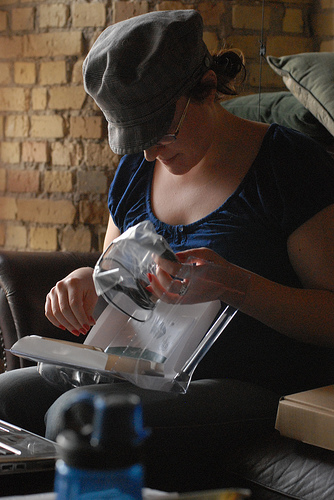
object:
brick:
[0, 86, 29, 117]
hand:
[145, 241, 228, 309]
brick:
[110, 0, 151, 25]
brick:
[34, 0, 69, 31]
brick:
[17, 196, 79, 228]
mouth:
[155, 149, 181, 169]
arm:
[0, 247, 102, 376]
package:
[91, 218, 213, 395]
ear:
[201, 71, 217, 110]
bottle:
[53, 385, 152, 497]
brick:
[37, 57, 72, 90]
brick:
[4, 112, 32, 143]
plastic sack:
[91, 217, 182, 323]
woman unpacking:
[0, 8, 333, 460]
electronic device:
[5, 258, 238, 399]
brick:
[1, 223, 30, 252]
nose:
[142, 141, 158, 164]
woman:
[0, 8, 333, 473]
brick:
[0, 62, 16, 86]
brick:
[27, 88, 49, 116]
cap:
[81, 9, 204, 158]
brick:
[65, 113, 104, 143]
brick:
[0, 34, 22, 62]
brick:
[66, 55, 89, 87]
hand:
[43, 266, 101, 340]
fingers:
[67, 280, 92, 334]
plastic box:
[6, 219, 224, 399]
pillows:
[264, 51, 332, 136]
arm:
[228, 205, 333, 348]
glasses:
[153, 86, 194, 151]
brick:
[45, 81, 88, 113]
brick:
[12, 58, 40, 89]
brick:
[261, 35, 308, 61]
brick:
[24, 26, 84, 62]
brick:
[8, 3, 36, 38]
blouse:
[107, 123, 334, 383]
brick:
[57, 224, 93, 256]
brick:
[25, 225, 59, 253]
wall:
[0, 0, 333, 260]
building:
[0, 0, 333, 498]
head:
[81, 5, 245, 177]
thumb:
[171, 243, 212, 265]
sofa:
[0, 251, 332, 497]